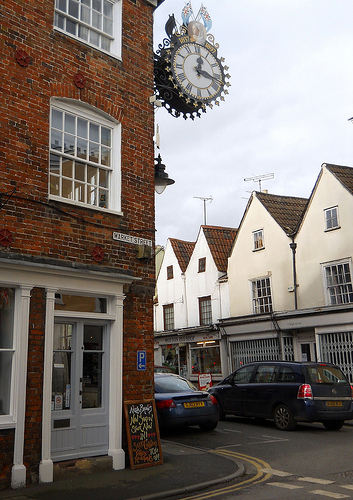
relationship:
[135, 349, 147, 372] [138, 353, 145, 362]
sign has p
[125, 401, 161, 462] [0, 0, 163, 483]
menu on shop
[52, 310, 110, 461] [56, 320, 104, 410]
door has windows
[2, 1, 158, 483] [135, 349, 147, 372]
shop on sign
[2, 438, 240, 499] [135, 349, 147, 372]
sidewalk next to sign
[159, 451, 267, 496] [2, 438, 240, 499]
line near sidewalk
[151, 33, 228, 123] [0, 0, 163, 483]
clock on shop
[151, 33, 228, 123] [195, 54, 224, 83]
clock has hands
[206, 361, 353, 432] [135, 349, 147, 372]
van on sign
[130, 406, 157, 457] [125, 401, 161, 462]
writing on menu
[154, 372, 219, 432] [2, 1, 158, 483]
car next to shop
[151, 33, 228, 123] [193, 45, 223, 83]
clock says 12:15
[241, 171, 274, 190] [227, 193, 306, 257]
antenna on roofs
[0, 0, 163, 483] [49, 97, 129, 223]
shop has windows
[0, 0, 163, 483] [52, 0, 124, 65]
shop has windows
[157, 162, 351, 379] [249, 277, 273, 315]
building has windows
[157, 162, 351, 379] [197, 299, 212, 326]
building has windows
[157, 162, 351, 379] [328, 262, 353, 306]
building has windows